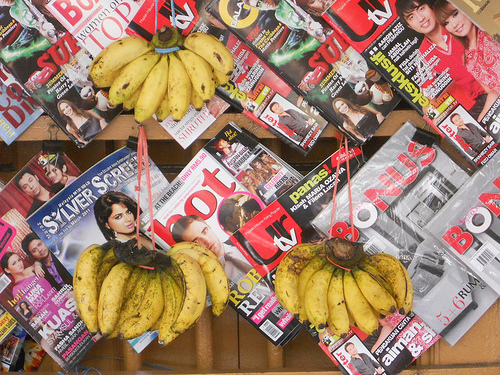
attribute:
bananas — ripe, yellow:
[72, 241, 223, 351]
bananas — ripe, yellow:
[276, 221, 413, 344]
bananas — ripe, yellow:
[89, 31, 232, 118]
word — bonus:
[327, 140, 437, 245]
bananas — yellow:
[278, 245, 403, 331]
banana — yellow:
[275, 240, 317, 325]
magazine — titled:
[30, 176, 175, 254]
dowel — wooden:
[193, 306, 213, 373]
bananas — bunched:
[89, 36, 251, 106]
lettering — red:
[145, 216, 189, 251]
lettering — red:
[179, 185, 222, 220]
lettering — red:
[196, 165, 237, 197]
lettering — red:
[362, 175, 405, 215]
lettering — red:
[385, 150, 422, 185]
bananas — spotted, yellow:
[44, 214, 241, 344]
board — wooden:
[3, 111, 498, 145]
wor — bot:
[147, 164, 249, 249]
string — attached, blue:
[151, 1, 185, 56]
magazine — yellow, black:
[196, 1, 498, 173]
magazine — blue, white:
[211, 129, 281, 181]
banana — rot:
[72, 238, 107, 334]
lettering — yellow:
[369, 50, 431, 107]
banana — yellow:
[352, 262, 397, 315]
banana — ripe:
[272, 238, 322, 318]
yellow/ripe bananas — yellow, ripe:
[85, 23, 250, 117]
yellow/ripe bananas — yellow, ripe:
[68, 219, 242, 346]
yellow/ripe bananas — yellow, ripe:
[276, 217, 422, 357]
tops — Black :
[110, 240, 172, 269]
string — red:
[328, 135, 355, 242]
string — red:
[135, 125, 156, 250]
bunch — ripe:
[271, 237, 412, 339]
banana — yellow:
[75, 237, 228, 344]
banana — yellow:
[274, 242, 414, 336]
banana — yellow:
[90, 26, 233, 124]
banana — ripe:
[351, 264, 400, 317]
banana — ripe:
[370, 252, 413, 314]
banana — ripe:
[296, 251, 328, 325]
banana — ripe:
[327, 265, 352, 337]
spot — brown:
[336, 296, 347, 309]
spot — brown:
[285, 251, 309, 276]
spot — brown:
[390, 290, 401, 300]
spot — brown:
[282, 286, 292, 303]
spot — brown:
[312, 294, 323, 304]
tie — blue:
[149, 42, 185, 56]